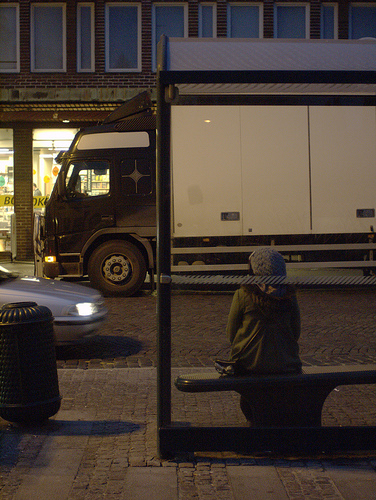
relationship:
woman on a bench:
[214, 246, 309, 378] [176, 362, 375, 430]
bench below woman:
[176, 362, 375, 430] [214, 246, 309, 378]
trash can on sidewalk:
[0, 297, 64, 426] [5, 364, 373, 498]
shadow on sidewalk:
[8, 416, 153, 441] [5, 364, 373, 498]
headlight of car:
[70, 302, 102, 318] [5, 262, 108, 350]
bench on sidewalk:
[176, 362, 375, 430] [5, 364, 373, 498]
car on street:
[5, 262, 108, 350] [1, 279, 374, 369]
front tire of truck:
[83, 236, 148, 299] [37, 36, 373, 296]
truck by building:
[37, 36, 373, 296] [0, 0, 373, 264]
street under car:
[1, 279, 374, 369] [5, 262, 108, 350]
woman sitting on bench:
[214, 246, 309, 378] [176, 362, 375, 430]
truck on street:
[37, 36, 373, 296] [1, 279, 374, 369]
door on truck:
[52, 159, 119, 243] [37, 36, 373, 296]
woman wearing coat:
[214, 246, 309, 378] [216, 282, 303, 374]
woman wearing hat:
[214, 246, 309, 378] [247, 245, 288, 287]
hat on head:
[247, 245, 288, 287] [241, 247, 288, 293]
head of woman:
[241, 247, 288, 293] [214, 246, 309, 378]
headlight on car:
[70, 302, 102, 318] [5, 262, 108, 350]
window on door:
[68, 160, 111, 196] [52, 159, 119, 243]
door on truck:
[52, 159, 119, 243] [31, 85, 374, 298]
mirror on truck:
[55, 169, 67, 201] [31, 85, 374, 298]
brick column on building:
[9, 121, 38, 263] [0, 0, 373, 264]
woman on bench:
[214, 246, 309, 378] [176, 362, 375, 430]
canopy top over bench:
[160, 35, 375, 74] [176, 362, 375, 430]